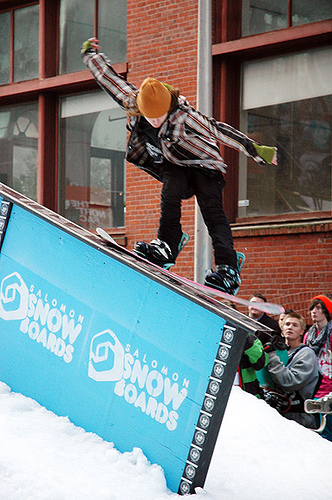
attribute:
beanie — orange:
[130, 72, 171, 116]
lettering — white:
[107, 341, 190, 432]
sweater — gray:
[242, 337, 319, 405]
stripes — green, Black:
[231, 337, 278, 393]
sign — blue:
[26, 257, 201, 496]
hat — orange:
[136, 74, 171, 121]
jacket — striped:
[119, 121, 225, 181]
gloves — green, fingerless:
[77, 36, 93, 57]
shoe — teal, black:
[130, 230, 173, 275]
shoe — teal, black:
[201, 257, 242, 307]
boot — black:
[126, 212, 200, 283]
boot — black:
[206, 245, 240, 300]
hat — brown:
[133, 73, 177, 123]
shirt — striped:
[163, 114, 227, 179]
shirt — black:
[131, 121, 181, 173]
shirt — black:
[142, 127, 181, 175]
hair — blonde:
[283, 310, 302, 323]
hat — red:
[315, 295, 330, 308]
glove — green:
[255, 140, 274, 165]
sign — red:
[55, 179, 117, 232]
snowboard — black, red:
[87, 219, 288, 325]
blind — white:
[238, 55, 330, 106]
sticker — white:
[237, 195, 250, 209]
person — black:
[230, 290, 279, 396]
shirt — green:
[232, 288, 279, 402]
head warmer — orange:
[306, 293, 331, 309]